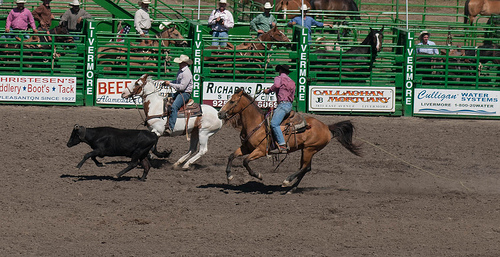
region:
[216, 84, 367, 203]
A horse in the picture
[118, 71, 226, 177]
A horse in the picture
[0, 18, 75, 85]
A horse in the picture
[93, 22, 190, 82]
A horse in the picture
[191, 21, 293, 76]
A horse in the picture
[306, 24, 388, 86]
A horse in the picture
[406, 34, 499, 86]
A horse in the picture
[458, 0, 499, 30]
A horse in the picture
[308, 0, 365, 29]
A horse in the picture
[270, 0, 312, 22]
A horse in the picture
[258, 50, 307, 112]
a man wearing a red shirt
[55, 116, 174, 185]
a small black cow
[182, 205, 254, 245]
dirt on the ground of the stable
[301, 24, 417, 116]
a tall green fence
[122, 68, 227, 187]
a white horse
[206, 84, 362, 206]
a brown horse running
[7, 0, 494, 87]
men standing behind the fence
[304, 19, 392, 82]
a black horse with a white stripe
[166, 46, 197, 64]
a white cowboy hat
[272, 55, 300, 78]
black cowboy hat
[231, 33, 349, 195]
man riding a horse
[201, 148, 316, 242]
legs of the horse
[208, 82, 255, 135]
head of the horse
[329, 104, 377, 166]
tail of the horse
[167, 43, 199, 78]
hat on the man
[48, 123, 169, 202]
black animal running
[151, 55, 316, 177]
white and brown horses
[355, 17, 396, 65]
horse behind a green gate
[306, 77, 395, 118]
advertisement on the wall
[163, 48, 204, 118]
man wearing jeans and a cowboy hat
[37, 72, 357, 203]
three horses are running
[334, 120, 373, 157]
tail on brown horse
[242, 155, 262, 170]
knee on brown horse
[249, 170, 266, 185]
a hoof on the horse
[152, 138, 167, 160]
tail on the bull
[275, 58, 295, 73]
black hat on man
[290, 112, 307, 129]
part of the horse saddle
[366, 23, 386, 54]
face of a horse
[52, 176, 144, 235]
dirt in the field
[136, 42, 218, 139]
man riding on horse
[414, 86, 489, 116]
an advertisement on wall